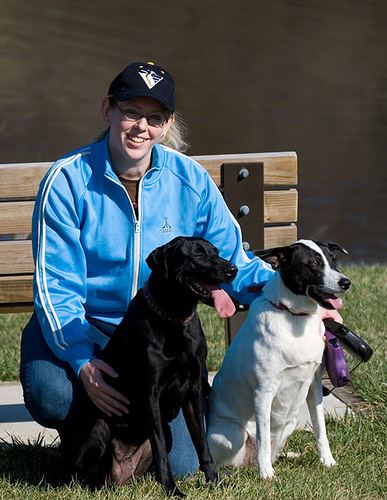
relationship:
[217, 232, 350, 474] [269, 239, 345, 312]
dog with head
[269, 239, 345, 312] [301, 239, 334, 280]
head with streak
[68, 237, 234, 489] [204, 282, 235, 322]
dog has tongue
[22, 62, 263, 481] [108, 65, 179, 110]
woman wearing hat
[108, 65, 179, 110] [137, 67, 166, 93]
hat with logo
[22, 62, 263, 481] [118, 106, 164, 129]
woman wearing glasses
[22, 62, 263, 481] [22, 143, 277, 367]
woman wearing jacket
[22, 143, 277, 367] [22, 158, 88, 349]
jacket with stripes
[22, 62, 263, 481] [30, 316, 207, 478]
woman wearing jeans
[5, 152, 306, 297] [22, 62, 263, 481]
bench behind woman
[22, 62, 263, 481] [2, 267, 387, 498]
woman kneeling on grass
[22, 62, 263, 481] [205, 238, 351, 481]
woman with dog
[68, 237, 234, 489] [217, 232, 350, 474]
dog left of dog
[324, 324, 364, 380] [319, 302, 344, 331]
leads in hand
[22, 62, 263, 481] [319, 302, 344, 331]
woman with hand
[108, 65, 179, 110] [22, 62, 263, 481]
hat on head of woman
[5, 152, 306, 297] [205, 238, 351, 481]
bench behind dog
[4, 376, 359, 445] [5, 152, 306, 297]
concrete under bench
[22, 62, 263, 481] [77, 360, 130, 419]
woman has right hand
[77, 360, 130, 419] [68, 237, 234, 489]
right hand on top of dog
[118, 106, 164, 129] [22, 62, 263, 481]
glasses over woman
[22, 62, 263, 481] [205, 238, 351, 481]
woman and dog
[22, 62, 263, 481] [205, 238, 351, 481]
woman holding dog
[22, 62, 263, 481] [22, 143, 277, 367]
woman has jacket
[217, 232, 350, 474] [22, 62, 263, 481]
dog in front of woman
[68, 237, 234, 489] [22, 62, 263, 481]
dog in front of woman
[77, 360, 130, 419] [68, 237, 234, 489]
right hand touching dog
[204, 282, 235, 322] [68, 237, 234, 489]
tongue sticking out of dog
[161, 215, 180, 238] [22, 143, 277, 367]
logo on front of jacket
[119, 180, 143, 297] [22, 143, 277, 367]
zipper of jacket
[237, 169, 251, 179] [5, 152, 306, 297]
bolt of bench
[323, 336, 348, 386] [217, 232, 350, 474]
leash next to dog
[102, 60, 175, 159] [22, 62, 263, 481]
head of woman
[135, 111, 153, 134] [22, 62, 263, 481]
nose of woman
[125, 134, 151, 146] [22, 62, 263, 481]
mouth of woman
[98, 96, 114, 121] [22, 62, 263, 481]
ear of woman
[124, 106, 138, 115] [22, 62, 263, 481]
eye of woman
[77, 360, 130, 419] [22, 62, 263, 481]
right hand of woman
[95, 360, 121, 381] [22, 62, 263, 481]
thumb of woman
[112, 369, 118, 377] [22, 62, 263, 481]
thumbnail of woman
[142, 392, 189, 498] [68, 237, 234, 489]
leg of dog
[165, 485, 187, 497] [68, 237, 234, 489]
paw of dog